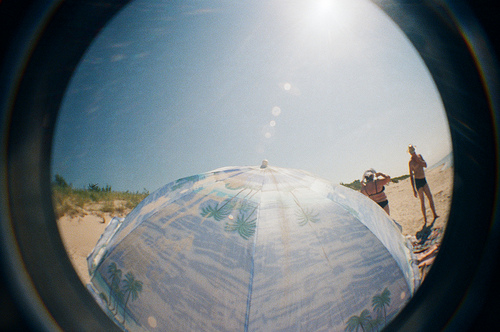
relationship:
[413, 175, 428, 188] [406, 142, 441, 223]
shorts on man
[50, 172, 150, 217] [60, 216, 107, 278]
grass on sand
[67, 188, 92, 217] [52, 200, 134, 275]
grass in sand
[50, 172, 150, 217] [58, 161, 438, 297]
grass in sand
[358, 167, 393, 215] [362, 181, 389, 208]
woman wears bathing suit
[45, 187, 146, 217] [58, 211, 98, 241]
patch in sand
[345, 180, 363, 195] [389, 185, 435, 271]
green grass in sand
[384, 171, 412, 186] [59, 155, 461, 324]
grass in sand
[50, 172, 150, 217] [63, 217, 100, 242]
grass in sand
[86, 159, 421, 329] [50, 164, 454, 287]
umbrella on beach